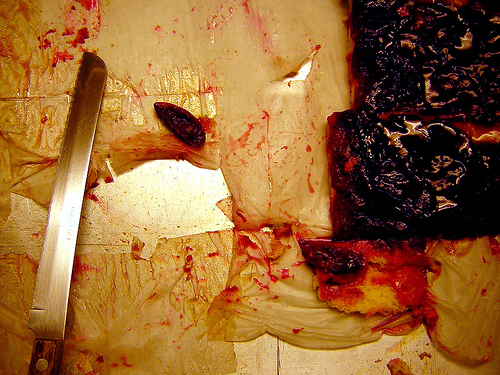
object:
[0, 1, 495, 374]
table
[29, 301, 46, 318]
notch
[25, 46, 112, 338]
blade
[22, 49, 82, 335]
edge